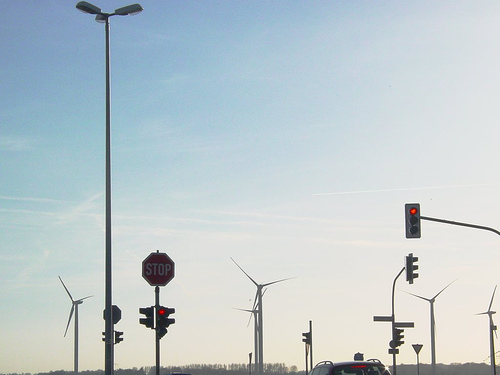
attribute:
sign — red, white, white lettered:
[141, 253, 173, 286]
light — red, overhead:
[157, 308, 166, 316]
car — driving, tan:
[311, 359, 391, 374]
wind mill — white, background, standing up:
[59, 276, 92, 375]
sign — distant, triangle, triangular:
[413, 344, 422, 354]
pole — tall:
[104, 24, 113, 375]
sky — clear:
[1, 0, 500, 373]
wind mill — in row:
[232, 259, 286, 375]